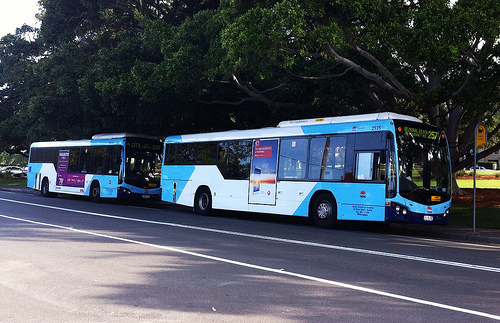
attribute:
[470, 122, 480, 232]
pole — metal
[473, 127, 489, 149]
street sign — yellow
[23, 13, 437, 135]
trees — shadows 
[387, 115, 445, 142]
sign — green